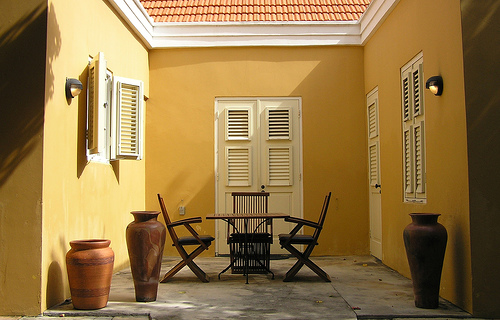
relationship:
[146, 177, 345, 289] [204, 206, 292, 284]
three chairs next to table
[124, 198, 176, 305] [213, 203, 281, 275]
vases next to table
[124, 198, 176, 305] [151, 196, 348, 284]
vases next to chairs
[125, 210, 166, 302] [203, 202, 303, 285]
vases are around table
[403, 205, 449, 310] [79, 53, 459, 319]
vase in patio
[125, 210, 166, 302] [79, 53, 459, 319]
vases in patio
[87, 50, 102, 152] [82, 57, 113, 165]
shutter on window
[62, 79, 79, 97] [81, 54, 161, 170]
light next to window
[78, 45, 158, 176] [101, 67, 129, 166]
shutters are on window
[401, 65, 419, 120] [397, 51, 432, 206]
shutters are on window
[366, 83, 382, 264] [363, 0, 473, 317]
white door on wall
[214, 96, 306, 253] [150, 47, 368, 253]
door on wall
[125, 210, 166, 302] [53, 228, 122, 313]
vases next to vase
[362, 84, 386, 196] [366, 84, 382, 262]
blinds on white door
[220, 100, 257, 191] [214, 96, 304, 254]
blinds on door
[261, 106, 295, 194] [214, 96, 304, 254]
blinds on door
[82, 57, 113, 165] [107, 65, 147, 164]
window has shutter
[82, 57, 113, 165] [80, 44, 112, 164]
window has shutter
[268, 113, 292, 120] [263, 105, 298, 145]
slat on shutter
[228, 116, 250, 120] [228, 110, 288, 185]
wooden slat on shutter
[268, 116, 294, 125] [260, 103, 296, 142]
wooden slat on shutter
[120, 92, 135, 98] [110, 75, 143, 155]
slat on shutter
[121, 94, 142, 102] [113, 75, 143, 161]
wooden slat on shutter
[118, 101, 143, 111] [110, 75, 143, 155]
wooden slat on shutter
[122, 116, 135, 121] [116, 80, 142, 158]
slat on shutter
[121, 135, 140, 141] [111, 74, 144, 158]
slat on shutter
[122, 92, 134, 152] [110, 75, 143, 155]
wooden slat on shutter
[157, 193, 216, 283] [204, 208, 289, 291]
chair at table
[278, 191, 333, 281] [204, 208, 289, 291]
chair at table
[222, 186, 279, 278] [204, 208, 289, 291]
chair at table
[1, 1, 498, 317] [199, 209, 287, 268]
house exterior with table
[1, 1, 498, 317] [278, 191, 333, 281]
house exterior with chair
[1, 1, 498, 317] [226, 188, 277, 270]
house exterior with chair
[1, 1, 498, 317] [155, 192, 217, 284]
house exterior with chair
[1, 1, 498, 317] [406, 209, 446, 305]
house exterior with vase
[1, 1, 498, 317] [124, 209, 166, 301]
house exterior with vase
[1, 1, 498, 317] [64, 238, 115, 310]
house exterior with vase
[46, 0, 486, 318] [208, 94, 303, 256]
outdoor patio with door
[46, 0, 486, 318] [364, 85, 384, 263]
outdoor patio with door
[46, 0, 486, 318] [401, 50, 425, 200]
outdoor patio with window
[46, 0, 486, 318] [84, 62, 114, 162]
outdoor patio with window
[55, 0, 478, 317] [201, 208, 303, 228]
patio with table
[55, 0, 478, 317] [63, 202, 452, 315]
patio with vases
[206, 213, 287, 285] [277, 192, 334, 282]
table with chair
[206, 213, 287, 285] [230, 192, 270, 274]
table with chair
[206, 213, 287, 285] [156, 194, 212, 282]
table with chair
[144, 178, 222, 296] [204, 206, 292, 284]
chair at table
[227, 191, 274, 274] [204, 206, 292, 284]
chair at table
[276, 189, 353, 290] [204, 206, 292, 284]
chair at table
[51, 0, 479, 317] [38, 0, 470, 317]
courtyard with walls